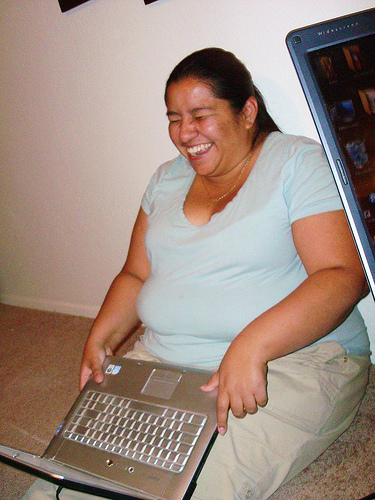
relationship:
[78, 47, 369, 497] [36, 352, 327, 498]
woman has lap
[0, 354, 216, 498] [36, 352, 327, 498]
laptop in lap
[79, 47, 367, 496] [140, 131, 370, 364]
woman wearing shirt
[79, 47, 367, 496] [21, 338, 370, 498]
woman wearing pants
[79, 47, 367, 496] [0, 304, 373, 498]
woman sitting on floor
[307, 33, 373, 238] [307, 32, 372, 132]
screen has corner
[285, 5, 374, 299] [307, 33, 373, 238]
laptop has screen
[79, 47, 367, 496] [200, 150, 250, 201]
woman wearing necklace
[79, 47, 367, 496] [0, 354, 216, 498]
woman has laptop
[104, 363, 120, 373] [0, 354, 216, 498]
stickers on laptop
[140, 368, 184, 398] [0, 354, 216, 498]
touchpad on laptop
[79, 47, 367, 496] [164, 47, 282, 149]
woman has hair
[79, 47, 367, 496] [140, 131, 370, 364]
woman has shirt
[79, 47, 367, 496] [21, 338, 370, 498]
woman wears pants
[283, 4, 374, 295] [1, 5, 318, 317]
laptop taking picture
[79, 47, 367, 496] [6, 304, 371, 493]
woman sitting on chair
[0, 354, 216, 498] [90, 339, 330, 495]
laptop on lap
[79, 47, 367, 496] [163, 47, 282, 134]
woman has hair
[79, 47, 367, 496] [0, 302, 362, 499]
woman sitting on carpet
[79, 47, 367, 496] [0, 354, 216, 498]
woman holding a laptop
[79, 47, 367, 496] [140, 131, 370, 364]
woman wearing a shirt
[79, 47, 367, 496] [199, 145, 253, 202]
woman wearing a necklace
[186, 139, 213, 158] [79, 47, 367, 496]
mouth of woman